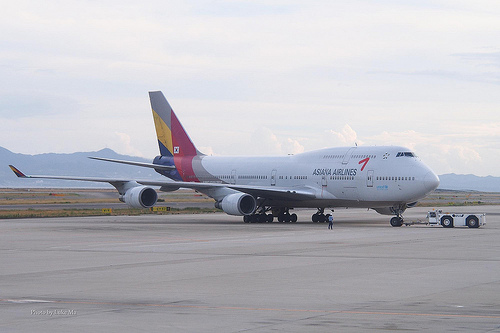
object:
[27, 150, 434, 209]
jet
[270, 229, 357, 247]
ground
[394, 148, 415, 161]
windshield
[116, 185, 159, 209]
engine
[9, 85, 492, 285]
plane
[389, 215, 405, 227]
wheel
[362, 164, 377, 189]
door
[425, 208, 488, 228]
truck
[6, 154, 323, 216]
wing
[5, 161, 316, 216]
right wing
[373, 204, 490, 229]
gate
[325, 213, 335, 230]
person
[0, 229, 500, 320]
runway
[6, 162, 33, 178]
winglet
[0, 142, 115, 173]
mountain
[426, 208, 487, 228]
cart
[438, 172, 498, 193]
hazy mountain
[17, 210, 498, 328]
tarmack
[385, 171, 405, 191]
windows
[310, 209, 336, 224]
gear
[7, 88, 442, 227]
airplane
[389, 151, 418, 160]
cockpit area